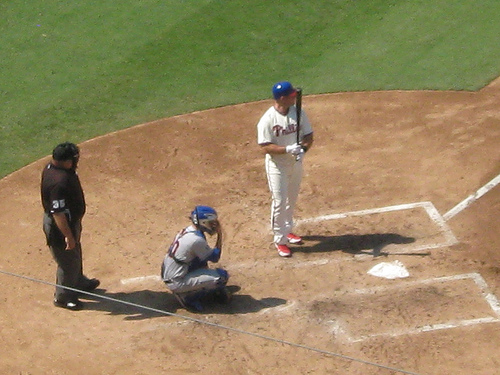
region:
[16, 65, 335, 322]
men playing baseball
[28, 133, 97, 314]
this man is wearing black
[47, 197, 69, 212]
the number 35 on his sleeve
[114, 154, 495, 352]
white lines on the ground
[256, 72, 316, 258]
this man is holding a bat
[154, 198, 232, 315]
this man is crouching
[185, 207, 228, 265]
he is touching his helmet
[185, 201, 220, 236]
his helmet is blue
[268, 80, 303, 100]
he is wearing a baseball cap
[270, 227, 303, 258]
his shoes are red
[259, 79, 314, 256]
baseball player holding bat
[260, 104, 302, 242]
white and red baseball uniform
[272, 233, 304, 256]
red and white baseball cleats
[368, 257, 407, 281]
a white homeplate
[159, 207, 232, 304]
a grey and blue baseball uniform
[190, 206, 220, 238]
blue catcher's helmet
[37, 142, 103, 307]
a heavy set baseball umpire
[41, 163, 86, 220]
black short sleeve shirt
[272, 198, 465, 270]
left side batter's box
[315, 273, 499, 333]
right side btter's box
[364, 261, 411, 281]
A white home plate.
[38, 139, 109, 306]
An umpire.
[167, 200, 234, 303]
A catcher.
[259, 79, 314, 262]
A batter.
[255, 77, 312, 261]
A baseball player.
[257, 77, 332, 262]
A man standing and holding a baseball bat.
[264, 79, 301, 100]
A blue helmet.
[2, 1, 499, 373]
Part of the baseball field.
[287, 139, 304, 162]
White baseball gloves.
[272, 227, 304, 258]
Red and white sneakers.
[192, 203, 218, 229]
blue plastic catchers helmet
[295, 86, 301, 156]
black metal baseball bat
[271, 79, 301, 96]
blue and red batting helmet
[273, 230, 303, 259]
red and white cleats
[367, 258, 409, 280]
white rubber home plate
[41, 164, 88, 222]
black cotton tee shirt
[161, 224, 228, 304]
blue red and grey baseball uniform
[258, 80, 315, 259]
man holding baseball bat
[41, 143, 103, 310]
man standing on baseball field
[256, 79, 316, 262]
Phillies baseball player at the plate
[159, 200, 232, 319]
Catcher with hand on mask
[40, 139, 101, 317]
Umpire standing behind catcher.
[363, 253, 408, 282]
Base designating home plate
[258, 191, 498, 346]
Batter's box marked with white chalk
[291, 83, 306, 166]
Bat in player's hands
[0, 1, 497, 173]
Green grass in playing field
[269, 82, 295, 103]
Blue batting helmet on batter's head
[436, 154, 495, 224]
White base line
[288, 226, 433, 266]
Batter's shadow in the dirt